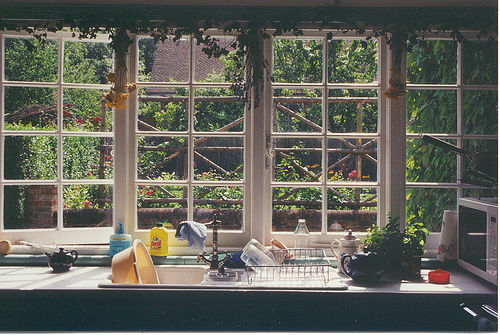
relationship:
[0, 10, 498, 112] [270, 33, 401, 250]
plants hanging above window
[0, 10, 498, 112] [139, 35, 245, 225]
plants hanging above window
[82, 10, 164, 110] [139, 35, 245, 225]
plants hanging above window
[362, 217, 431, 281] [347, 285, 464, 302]
houseplant growing on counter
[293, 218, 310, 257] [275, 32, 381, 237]
bottle beside window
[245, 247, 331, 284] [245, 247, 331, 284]
dish drying on dish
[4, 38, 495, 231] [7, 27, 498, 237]
plants seen through window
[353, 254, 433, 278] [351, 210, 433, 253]
pot has a plant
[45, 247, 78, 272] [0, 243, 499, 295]
tea pot on counter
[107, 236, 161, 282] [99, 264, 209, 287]
bain in sink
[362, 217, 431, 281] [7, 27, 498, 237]
houseplant beside window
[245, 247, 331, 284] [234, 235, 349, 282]
dish has bottles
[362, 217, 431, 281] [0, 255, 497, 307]
houseplant on counter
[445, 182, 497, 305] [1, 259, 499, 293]
microoven on counter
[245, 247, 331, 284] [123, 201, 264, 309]
dish on sink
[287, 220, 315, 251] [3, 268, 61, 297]
jar on counter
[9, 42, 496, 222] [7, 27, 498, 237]
plants are behind window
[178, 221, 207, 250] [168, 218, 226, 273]
dish cloth on top of faucet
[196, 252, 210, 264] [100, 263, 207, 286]
handle of sink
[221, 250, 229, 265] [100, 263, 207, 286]
handle of sink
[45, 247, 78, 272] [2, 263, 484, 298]
tea pot on counter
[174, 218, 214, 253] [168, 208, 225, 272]
dish cloth hanging on faucet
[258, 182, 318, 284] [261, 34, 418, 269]
bottle near window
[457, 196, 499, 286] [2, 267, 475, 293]
microoven on counter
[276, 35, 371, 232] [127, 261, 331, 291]
window above sink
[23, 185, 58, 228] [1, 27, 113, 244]
pillar outside of window